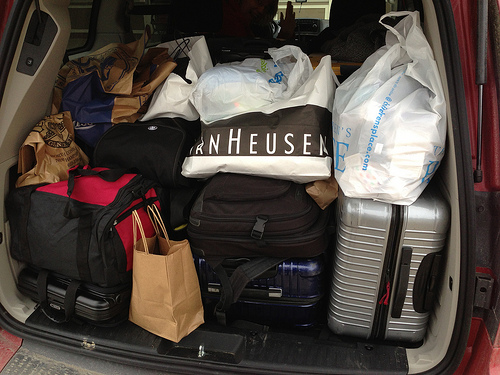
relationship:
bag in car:
[325, 12, 447, 207] [0, 0, 499, 375]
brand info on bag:
[187, 130, 334, 155] [180, 51, 339, 183]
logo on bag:
[27, 127, 79, 148] [12, 108, 92, 186]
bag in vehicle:
[127, 203, 205, 344] [11, 39, 486, 361]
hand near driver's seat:
[278, 3, 300, 41] [196, 0, 270, 45]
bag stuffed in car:
[121, 198, 208, 342] [11, 6, 480, 362]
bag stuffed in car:
[325, 12, 447, 207] [11, 6, 480, 362]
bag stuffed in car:
[180, 51, 339, 183] [11, 6, 480, 362]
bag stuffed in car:
[188, 41, 314, 121] [11, 6, 480, 362]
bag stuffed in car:
[12, 108, 92, 186] [11, 6, 480, 362]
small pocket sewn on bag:
[201, 179, 302, 208] [184, 172, 330, 260]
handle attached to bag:
[128, 207, 149, 254] [121, 198, 208, 342]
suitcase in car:
[327, 189, 451, 350] [11, 6, 480, 362]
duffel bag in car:
[4, 165, 163, 289] [11, 6, 480, 362]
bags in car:
[40, 44, 422, 365] [11, 6, 480, 362]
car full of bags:
[11, 6, 480, 362] [24, 13, 449, 343]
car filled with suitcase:
[11, 6, 480, 362] [336, 190, 451, 352]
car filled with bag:
[11, 6, 480, 362] [184, 172, 330, 260]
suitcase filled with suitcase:
[336, 190, 451, 352] [190, 255, 323, 326]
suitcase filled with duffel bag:
[336, 190, 451, 352] [4, 165, 163, 289]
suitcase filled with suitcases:
[336, 190, 451, 352] [88, 119, 201, 186]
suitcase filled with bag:
[336, 190, 451, 352] [180, 44, 339, 185]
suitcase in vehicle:
[327, 189, 451, 350] [11, 39, 486, 361]